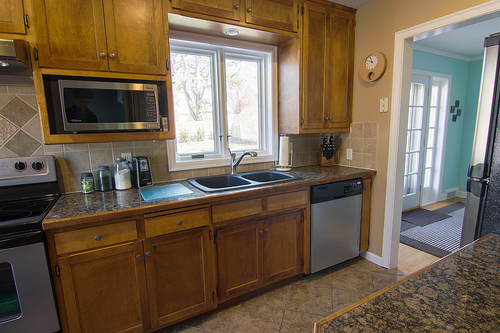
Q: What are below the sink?
A: Cabinets.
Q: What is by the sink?
A: Window.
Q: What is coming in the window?
A: Sunlight.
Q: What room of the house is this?
A: Kitchen.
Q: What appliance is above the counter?
A: Microwave.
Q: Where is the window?
A: Above the sink.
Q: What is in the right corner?
A: Refrigerator.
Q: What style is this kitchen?
A: Country.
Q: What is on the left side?
A: Stove.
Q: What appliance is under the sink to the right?
A: Dishwasher.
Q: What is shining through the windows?
A: Sunlight.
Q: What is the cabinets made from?
A: Wood.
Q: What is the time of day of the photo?
A: Daytime.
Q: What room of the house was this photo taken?
A: Kitchen.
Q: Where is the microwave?
A: Above counter.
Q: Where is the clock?
A: On wall.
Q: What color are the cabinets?
A: Brown.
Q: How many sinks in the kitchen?
A: Two.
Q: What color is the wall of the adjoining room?
A: Blue.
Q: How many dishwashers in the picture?
A: One.